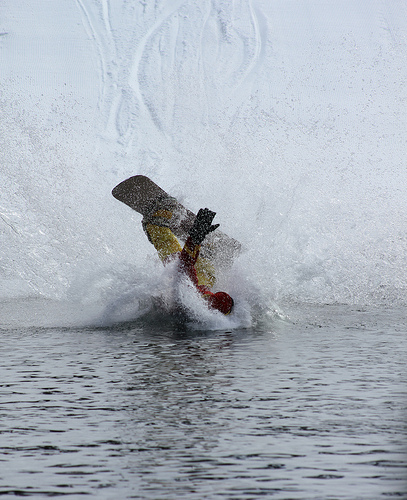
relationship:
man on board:
[131, 194, 235, 325] [103, 168, 248, 264]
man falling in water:
[131, 194, 235, 325] [0, 292, 405, 498]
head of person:
[206, 290, 237, 316] [135, 193, 238, 317]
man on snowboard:
[131, 194, 235, 325] [112, 174, 245, 269]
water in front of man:
[0, 292, 405, 498] [131, 194, 235, 325]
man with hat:
[131, 194, 235, 325] [210, 290, 234, 315]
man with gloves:
[131, 194, 240, 344] [184, 203, 227, 242]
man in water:
[131, 194, 235, 325] [8, 179, 390, 480]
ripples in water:
[2, 367, 133, 413] [0, 292, 405, 498]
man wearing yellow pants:
[131, 194, 235, 325] [140, 201, 183, 264]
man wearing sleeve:
[131, 194, 235, 325] [176, 237, 201, 304]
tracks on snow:
[83, 8, 283, 125] [2, 2, 396, 292]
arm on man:
[178, 208, 217, 276] [131, 194, 235, 325]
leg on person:
[141, 195, 189, 260] [136, 188, 224, 324]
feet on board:
[149, 198, 178, 221] [109, 173, 247, 266]